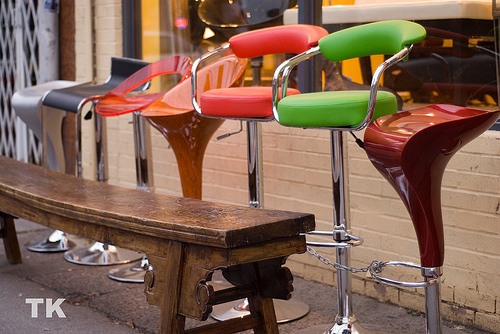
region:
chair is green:
[245, 24, 440, 201]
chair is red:
[220, 26, 304, 138]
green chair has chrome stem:
[277, 30, 377, 322]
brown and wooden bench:
[16, 147, 310, 328]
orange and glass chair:
[139, 68, 222, 222]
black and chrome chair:
[33, 46, 180, 256]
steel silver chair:
[18, 68, 81, 253]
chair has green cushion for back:
[297, 26, 397, 318]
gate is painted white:
[3, 8, 70, 250]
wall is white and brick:
[68, 6, 498, 313]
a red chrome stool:
[363, 42, 498, 329]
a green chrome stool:
[278, 14, 434, 330]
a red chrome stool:
[192, 19, 313, 329]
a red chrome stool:
[93, 51, 189, 282]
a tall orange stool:
[141, 48, 249, 298]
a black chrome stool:
[44, 51, 139, 268]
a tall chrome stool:
[12, 74, 85, 258]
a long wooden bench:
[1, 149, 311, 329]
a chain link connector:
[304, 240, 381, 277]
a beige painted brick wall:
[91, 86, 498, 324]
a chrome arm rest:
[188, 41, 228, 116]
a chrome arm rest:
[266, 43, 320, 116]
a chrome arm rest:
[359, 44, 406, 118]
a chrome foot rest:
[371, 251, 440, 286]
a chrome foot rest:
[288, 215, 364, 257]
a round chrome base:
[200, 277, 314, 330]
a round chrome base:
[104, 254, 161, 282]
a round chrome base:
[61, 238, 141, 266]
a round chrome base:
[27, 226, 69, 251]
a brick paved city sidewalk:
[0, 202, 494, 330]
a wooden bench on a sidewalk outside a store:
[2, 157, 319, 324]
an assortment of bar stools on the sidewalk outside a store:
[27, 14, 488, 190]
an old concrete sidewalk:
[30, 265, 126, 332]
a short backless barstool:
[366, 94, 474, 254]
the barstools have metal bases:
[40, 225, 142, 280]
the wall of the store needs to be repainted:
[455, 175, 497, 328]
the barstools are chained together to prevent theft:
[315, 220, 444, 291]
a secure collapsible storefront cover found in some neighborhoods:
[5, 2, 55, 84]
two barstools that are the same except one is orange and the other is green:
[190, 12, 416, 144]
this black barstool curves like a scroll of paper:
[41, 52, 150, 116]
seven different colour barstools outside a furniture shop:
[3, 19, 496, 332]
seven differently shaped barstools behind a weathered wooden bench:
[0, 148, 319, 332]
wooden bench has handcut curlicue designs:
[137, 255, 300, 325]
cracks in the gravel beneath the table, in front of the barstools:
[17, 265, 149, 331]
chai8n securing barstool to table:
[280, 247, 390, 282]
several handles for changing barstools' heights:
[76, 97, 366, 149]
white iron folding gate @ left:
[0, 0, 60, 171]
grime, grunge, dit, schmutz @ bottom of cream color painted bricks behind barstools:
[287, 252, 497, 332]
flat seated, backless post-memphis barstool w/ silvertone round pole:
[355, 100, 495, 330]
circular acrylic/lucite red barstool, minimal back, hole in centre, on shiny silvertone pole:
[96, 42, 196, 290]